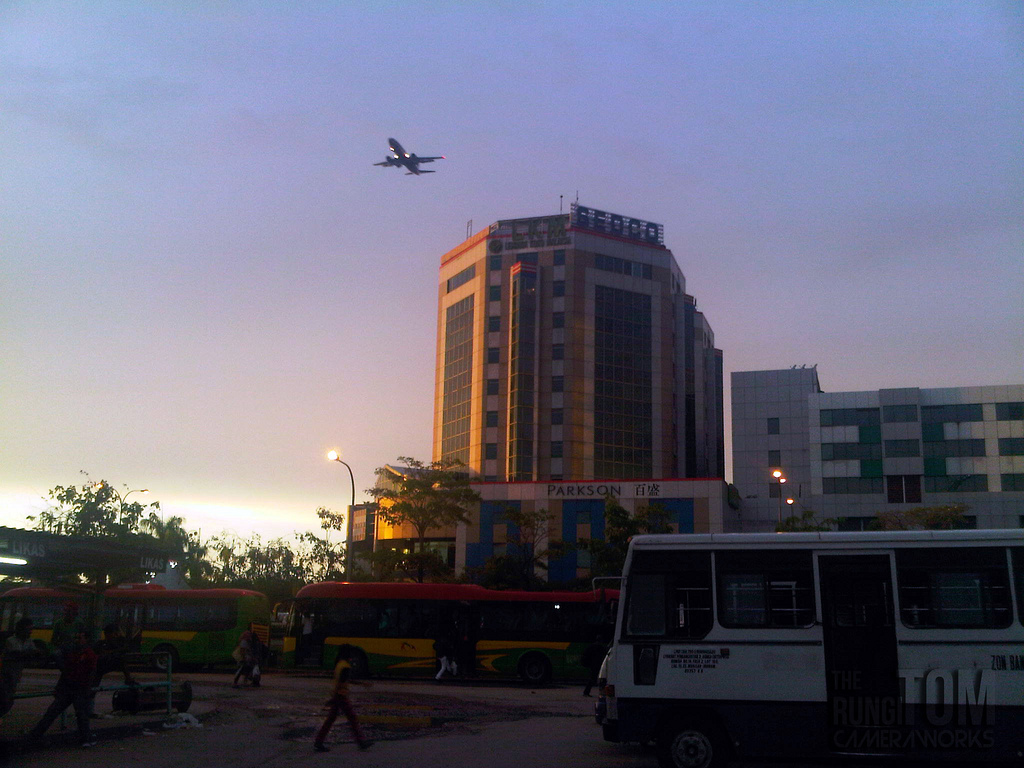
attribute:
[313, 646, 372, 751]
person — walking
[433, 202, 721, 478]
building — tall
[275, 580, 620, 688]
bus — yellow, red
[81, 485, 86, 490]
leaf — green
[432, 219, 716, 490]
building — red, white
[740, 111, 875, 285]
sky — colored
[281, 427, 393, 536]
streetlamps — illuminated 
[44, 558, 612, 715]
busses — red, gold, green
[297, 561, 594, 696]
bus — white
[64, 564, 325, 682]
bus — red, green, yellow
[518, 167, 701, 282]
letters — black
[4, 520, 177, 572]
logo — blue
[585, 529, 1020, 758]
bus — white, black